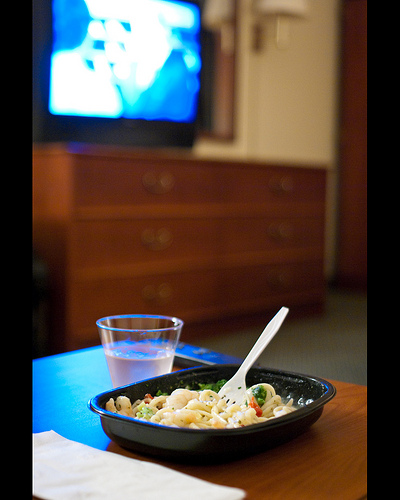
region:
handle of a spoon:
[251, 306, 284, 352]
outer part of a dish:
[184, 438, 215, 462]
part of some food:
[171, 384, 224, 425]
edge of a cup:
[122, 326, 157, 334]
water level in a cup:
[121, 352, 151, 364]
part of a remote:
[186, 346, 208, 362]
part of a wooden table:
[290, 469, 325, 498]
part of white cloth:
[86, 463, 142, 492]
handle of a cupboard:
[270, 220, 292, 237]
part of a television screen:
[76, 9, 198, 125]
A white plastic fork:
[216, 289, 286, 404]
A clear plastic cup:
[89, 300, 188, 374]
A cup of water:
[83, 309, 178, 381]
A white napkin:
[44, 423, 216, 498]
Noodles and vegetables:
[162, 384, 267, 417]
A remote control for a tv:
[182, 339, 234, 368]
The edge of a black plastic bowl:
[102, 402, 195, 440]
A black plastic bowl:
[100, 377, 349, 446]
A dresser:
[61, 141, 336, 310]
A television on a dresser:
[39, 24, 238, 182]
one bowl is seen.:
[102, 370, 274, 450]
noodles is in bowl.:
[132, 392, 248, 424]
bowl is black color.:
[168, 424, 240, 452]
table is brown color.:
[252, 452, 332, 484]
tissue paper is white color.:
[44, 456, 108, 488]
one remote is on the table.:
[180, 344, 224, 368]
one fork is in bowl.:
[212, 336, 265, 396]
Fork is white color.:
[220, 303, 289, 413]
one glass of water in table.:
[100, 316, 180, 392]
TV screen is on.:
[32, 11, 200, 136]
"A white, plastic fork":
[203, 302, 299, 414]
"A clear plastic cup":
[87, 312, 203, 386]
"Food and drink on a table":
[68, 311, 335, 459]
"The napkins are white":
[28, 420, 267, 499]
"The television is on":
[29, 5, 237, 160]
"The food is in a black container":
[80, 306, 361, 469]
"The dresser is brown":
[43, 134, 344, 328]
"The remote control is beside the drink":
[93, 308, 350, 467]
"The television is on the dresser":
[35, 0, 345, 337]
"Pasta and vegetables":
[89, 342, 351, 467]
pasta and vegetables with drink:
[70, 300, 335, 474]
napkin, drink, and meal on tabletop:
[37, 306, 285, 499]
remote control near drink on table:
[97, 311, 253, 375]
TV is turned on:
[39, 4, 253, 138]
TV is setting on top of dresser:
[31, 3, 329, 252]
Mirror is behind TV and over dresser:
[100, 6, 291, 201]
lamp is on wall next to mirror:
[238, 3, 348, 85]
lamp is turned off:
[238, 3, 355, 92]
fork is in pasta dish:
[91, 304, 396, 492]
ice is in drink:
[90, 295, 236, 408]